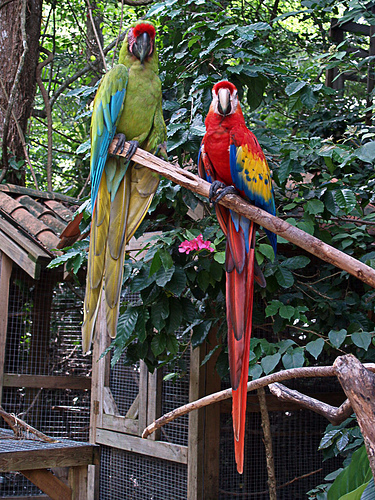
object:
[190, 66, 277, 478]
parrots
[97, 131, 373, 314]
stick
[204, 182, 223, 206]
claws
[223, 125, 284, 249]
wings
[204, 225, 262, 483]
tail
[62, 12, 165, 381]
parrot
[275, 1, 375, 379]
trees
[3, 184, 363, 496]
cages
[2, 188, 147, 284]
roof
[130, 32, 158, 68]
beak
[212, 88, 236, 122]
beak